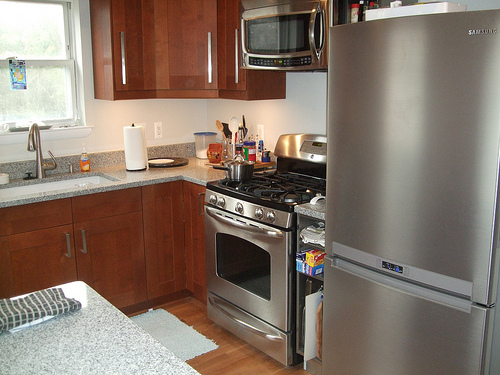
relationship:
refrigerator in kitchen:
[316, 11, 498, 372] [1, 1, 484, 371]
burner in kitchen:
[203, 172, 326, 228] [1, 1, 484, 371]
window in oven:
[216, 231, 276, 298] [205, 203, 292, 367]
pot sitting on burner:
[209, 155, 254, 181] [220, 175, 250, 192]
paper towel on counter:
[123, 126, 148, 170] [87, 152, 225, 191]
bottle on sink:
[74, 150, 94, 178] [3, 160, 110, 199]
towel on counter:
[0, 281, 82, 339] [1, 277, 202, 373]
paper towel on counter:
[123, 126, 148, 170] [103, 156, 234, 184]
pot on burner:
[209, 155, 254, 181] [203, 172, 326, 228]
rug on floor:
[129, 308, 218, 364] [141, 294, 291, 370]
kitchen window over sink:
[0, 1, 76, 128] [3, 156, 116, 206]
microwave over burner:
[240, 4, 331, 67] [203, 172, 326, 228]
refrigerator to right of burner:
[316, 11, 498, 372] [203, 172, 326, 228]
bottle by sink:
[80, 152, 90, 172] [0, 158, 117, 202]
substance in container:
[196, 145, 211, 158] [189, 128, 219, 163]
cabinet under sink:
[1, 181, 207, 314] [0, 158, 117, 202]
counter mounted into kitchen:
[0, 280, 200, 374] [1, 1, 484, 371]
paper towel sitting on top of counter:
[123, 126, 148, 170] [0, 142, 277, 208]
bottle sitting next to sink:
[80, 152, 90, 172] [1, 173, 119, 200]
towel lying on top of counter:
[0, 288, 81, 335] [1, 277, 202, 373]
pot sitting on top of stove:
[207, 156, 254, 185] [202, 164, 325, 214]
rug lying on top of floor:
[129, 308, 218, 364] [123, 296, 311, 373]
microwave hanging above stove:
[240, 4, 329, 72] [201, 166, 325, 229]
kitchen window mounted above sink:
[0, 1, 76, 128] [1, 173, 119, 200]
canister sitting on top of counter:
[192, 130, 218, 160] [0, 155, 280, 208]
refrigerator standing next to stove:
[322, 9, 499, 375] [201, 166, 325, 229]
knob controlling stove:
[206, 193, 217, 204] [201, 166, 325, 229]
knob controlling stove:
[214, 196, 226, 207] [201, 166, 325, 229]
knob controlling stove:
[232, 201, 242, 214] [201, 166, 325, 229]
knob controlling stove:
[252, 205, 263, 218] [201, 166, 325, 229]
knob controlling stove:
[265, 210, 275, 224] [201, 166, 325, 229]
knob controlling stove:
[254, 207, 264, 219] [201, 166, 325, 229]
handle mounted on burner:
[208, 297, 286, 344] [203, 172, 326, 228]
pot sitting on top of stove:
[209, 155, 254, 181] [201, 166, 325, 229]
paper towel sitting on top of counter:
[120, 122, 150, 172] [0, 155, 280, 208]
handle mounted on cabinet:
[61, 230, 72, 257] [1, 223, 77, 298]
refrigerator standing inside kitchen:
[322, 9, 499, 375] [1, 1, 484, 371]